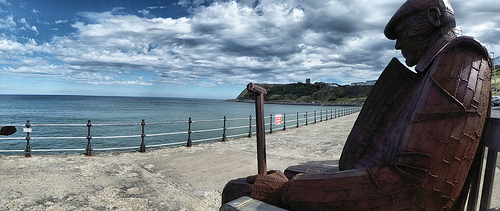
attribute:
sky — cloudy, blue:
[0, 0, 499, 99]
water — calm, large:
[0, 95, 362, 153]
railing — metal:
[2, 112, 499, 210]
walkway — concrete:
[1, 109, 499, 210]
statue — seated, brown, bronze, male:
[219, 1, 499, 209]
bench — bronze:
[219, 117, 499, 210]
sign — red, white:
[276, 113, 283, 126]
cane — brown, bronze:
[246, 81, 267, 174]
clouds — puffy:
[0, 1, 499, 85]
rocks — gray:
[223, 82, 375, 108]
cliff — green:
[226, 78, 378, 108]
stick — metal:
[247, 82, 267, 173]